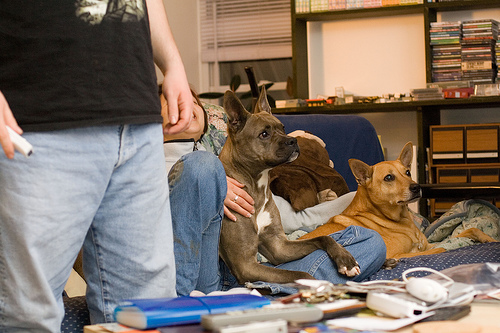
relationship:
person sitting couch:
[154, 71, 396, 294] [216, 100, 391, 180]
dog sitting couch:
[329, 139, 497, 265] [327, 118, 381, 157]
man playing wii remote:
[0, 1, 196, 333] [364, 292, 429, 318]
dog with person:
[204, 84, 360, 282] [157, 79, 384, 285]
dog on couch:
[204, 84, 360, 282] [221, 112, 498, 289]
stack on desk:
[429, 10, 458, 85] [283, 84, 484, 156]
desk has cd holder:
[424, 102, 496, 183] [431, 123, 498, 157]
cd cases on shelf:
[429, 20, 494, 89] [341, 77, 498, 111]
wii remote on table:
[346, 265, 454, 317] [81, 301, 497, 331]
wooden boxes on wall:
[430, 114, 482, 186] [350, 40, 440, 85]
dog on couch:
[296, 139, 497, 268] [295, 105, 498, 279]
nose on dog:
[410, 183, 421, 193] [296, 140, 498, 261]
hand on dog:
[222, 175, 257, 222] [206, 75, 344, 307]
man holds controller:
[0, 1, 195, 318] [6, 125, 34, 157]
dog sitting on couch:
[204, 84, 360, 282] [216, 108, 498, 271]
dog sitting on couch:
[296, 139, 497, 268] [293, 117, 372, 152]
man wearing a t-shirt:
[0, 1, 195, 318] [3, 0, 177, 128]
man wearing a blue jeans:
[0, 1, 196, 333] [2, 123, 179, 332]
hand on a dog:
[206, 170, 246, 216] [158, 100, 358, 279]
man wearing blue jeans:
[0, 1, 195, 318] [2, 114, 179, 330]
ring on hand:
[232, 191, 240, 203] [225, 181, 253, 222]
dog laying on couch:
[286, 140, 452, 261] [278, 108, 400, 198]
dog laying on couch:
[204, 84, 360, 275] [278, 108, 400, 198]